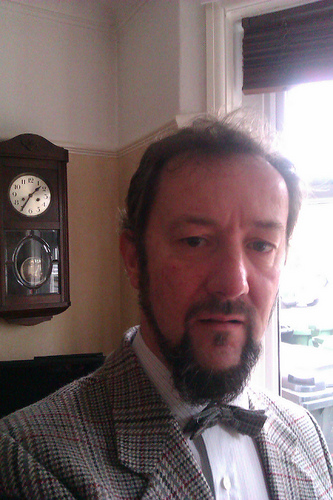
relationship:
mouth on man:
[198, 311, 244, 328] [0, 100, 332, 498]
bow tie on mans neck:
[187, 406, 269, 438] [136, 324, 240, 414]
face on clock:
[14, 181, 42, 211] [0, 143, 71, 296]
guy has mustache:
[1, 114, 331, 498] [177, 298, 258, 314]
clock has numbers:
[7, 172, 56, 221] [27, 206, 42, 214]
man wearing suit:
[0, 100, 332, 498] [1, 323, 332, 499]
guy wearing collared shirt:
[1, 114, 331, 498] [130, 328, 271, 498]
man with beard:
[0, 100, 332, 498] [138, 233, 284, 407]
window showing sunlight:
[202, 0, 332, 461] [278, 85, 331, 384]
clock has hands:
[0, 132, 71, 320] [20, 195, 30, 210]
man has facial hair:
[0, 100, 332, 498] [136, 294, 265, 404]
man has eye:
[0, 100, 332, 498] [179, 233, 210, 248]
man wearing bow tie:
[0, 100, 332, 498] [183, 402, 268, 440]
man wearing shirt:
[0, 100, 332, 498] [134, 336, 270, 497]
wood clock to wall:
[2, 130, 70, 316] [7, 18, 115, 356]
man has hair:
[0, 100, 332, 498] [118, 113, 274, 214]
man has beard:
[0, 100, 332, 498] [137, 263, 265, 409]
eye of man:
[178, 234, 209, 249] [0, 100, 332, 498]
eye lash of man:
[257, 239, 274, 244] [0, 100, 332, 498]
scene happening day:
[74, 23, 311, 336] [284, 152, 332, 382]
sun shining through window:
[282, 144, 331, 191] [202, 0, 332, 461]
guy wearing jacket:
[95, 143, 290, 408] [86, 384, 315, 483]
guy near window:
[55, 157, 319, 442] [267, 147, 332, 398]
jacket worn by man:
[71, 398, 161, 487] [58, 87, 328, 497]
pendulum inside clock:
[13, 242, 55, 288] [0, 132, 71, 320]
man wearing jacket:
[0, 100, 332, 498] [77, 394, 150, 460]